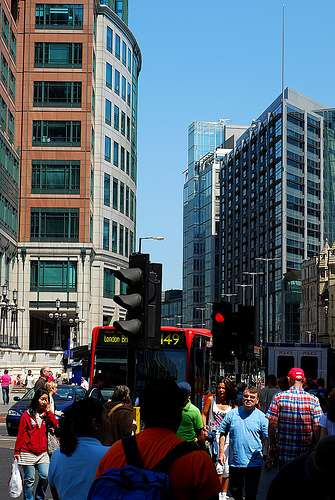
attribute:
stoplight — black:
[209, 296, 260, 368]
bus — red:
[85, 322, 266, 424]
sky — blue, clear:
[130, 4, 333, 297]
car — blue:
[3, 382, 85, 438]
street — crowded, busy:
[3, 426, 64, 497]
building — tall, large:
[213, 81, 333, 391]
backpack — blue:
[85, 461, 180, 499]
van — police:
[257, 338, 334, 396]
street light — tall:
[253, 249, 282, 345]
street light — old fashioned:
[45, 294, 71, 350]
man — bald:
[33, 364, 54, 394]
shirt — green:
[178, 403, 206, 447]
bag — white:
[9, 458, 25, 500]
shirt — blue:
[215, 402, 269, 469]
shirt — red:
[260, 382, 325, 471]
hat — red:
[284, 365, 311, 385]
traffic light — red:
[209, 307, 228, 328]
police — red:
[274, 347, 297, 359]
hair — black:
[25, 385, 54, 420]